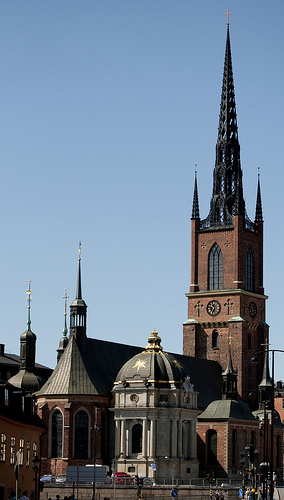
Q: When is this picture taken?
A: Daytime.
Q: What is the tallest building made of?
A: Bricks.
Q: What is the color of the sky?
A: Blue.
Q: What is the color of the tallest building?
A: Brick red.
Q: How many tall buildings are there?
A: One.